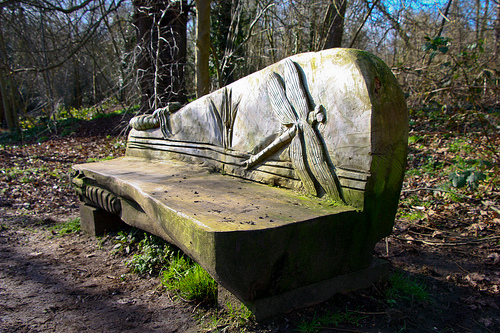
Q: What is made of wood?
A: Bench.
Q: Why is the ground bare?
A: Its winter.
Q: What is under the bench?
A: Grass.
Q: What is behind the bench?
A: Trees.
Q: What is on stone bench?
A: Dragonfly.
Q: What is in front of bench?
A: Flat dirt covered ground.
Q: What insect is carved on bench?
A: Dragonfly.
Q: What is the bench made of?
A: Stone.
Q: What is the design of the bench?
A: Sculptured dragonflies.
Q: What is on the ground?
A: Mud and soil.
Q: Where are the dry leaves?
A: On the ground.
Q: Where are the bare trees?
A: Behind the bench.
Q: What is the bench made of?
A: Stones.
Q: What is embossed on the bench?
A: Dragonfly and grass.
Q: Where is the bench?
A: In the forest.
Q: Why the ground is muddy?
A: The ground is wet.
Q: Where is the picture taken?
A: A park.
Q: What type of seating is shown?
A: Bench.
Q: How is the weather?
A: Sunny.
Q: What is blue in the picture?
A: Sky.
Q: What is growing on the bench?
A: Moss.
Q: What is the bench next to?
A: A path.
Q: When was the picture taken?
A: Morning.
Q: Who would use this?
A: Someone visiting the park.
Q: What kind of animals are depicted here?
A: Insects.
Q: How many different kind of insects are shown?
A: Three.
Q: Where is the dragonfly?
A: On the back of the bench.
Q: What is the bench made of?
A: Cement.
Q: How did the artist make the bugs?
A: By carving them.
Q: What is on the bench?
A: Moss.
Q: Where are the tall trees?
A: Behind the bench.